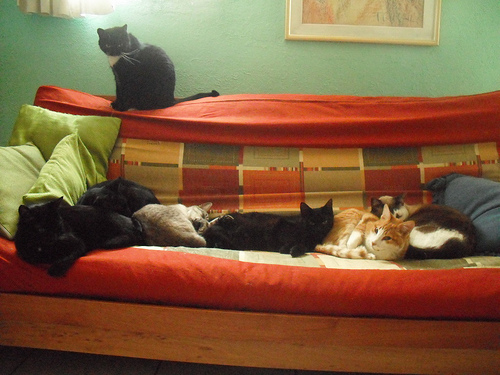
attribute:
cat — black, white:
[369, 191, 483, 261]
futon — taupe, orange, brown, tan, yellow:
[1, 80, 498, 362]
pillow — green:
[44, 134, 103, 207]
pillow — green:
[11, 96, 128, 162]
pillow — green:
[1, 146, 49, 232]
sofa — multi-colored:
[0, 82, 498, 370]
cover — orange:
[34, 83, 497, 139]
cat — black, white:
[93, 22, 218, 110]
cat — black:
[76, 175, 158, 215]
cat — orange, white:
[301, 199, 416, 261]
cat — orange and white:
[316, 202, 417, 265]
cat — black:
[13, 195, 135, 279]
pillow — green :
[22, 131, 96, 205]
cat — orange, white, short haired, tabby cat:
[315, 203, 404, 260]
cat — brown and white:
[373, 188, 477, 265]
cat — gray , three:
[149, 191, 210, 242]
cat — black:
[86, 18, 219, 117]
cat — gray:
[117, 185, 222, 255]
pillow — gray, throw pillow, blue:
[416, 172, 499, 252]